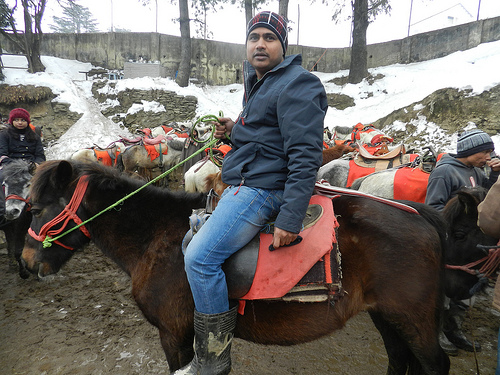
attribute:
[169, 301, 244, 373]
boot — black, grubby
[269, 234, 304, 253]
sunglasses — black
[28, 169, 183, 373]
horse — brown, small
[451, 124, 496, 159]
hat — white, blue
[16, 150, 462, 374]
horse — brown, black, solid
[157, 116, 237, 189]
animal — small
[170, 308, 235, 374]
boot — rubber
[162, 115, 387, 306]
saddle — pink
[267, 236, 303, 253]
object — brown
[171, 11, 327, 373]
man — young, dark skinned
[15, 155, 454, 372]
mule — small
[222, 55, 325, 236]
coat — blue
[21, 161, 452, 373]
pony — dark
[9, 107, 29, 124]
hat — red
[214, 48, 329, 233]
jacket — blue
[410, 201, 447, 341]
tail — black, thin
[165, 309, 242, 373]
boot — dirty, black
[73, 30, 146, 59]
wall — concrete, long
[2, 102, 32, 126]
cap — red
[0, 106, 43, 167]
person — small